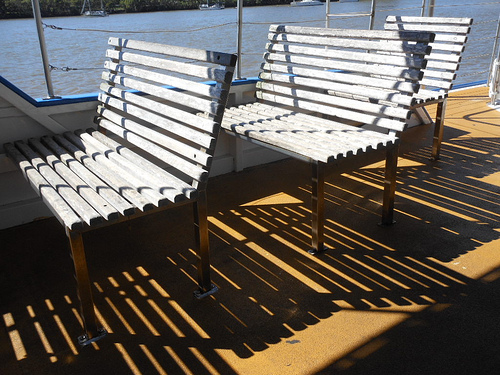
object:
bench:
[13, 36, 237, 346]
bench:
[208, 24, 433, 262]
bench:
[360, 14, 473, 162]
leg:
[65, 222, 99, 344]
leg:
[195, 194, 212, 295]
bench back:
[87, 36, 239, 166]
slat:
[99, 82, 207, 137]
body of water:
[0, 0, 488, 84]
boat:
[0, 0, 499, 375]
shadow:
[93, 215, 249, 375]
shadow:
[282, 165, 500, 263]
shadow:
[404, 139, 500, 192]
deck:
[7, 103, 500, 375]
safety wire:
[42, 21, 238, 34]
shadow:
[231, 25, 310, 128]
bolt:
[78, 335, 86, 340]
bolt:
[98, 328, 106, 333]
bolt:
[195, 289, 201, 294]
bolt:
[211, 283, 216, 287]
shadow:
[281, 205, 477, 306]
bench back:
[247, 24, 431, 131]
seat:
[21, 146, 193, 230]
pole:
[31, 0, 58, 101]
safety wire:
[47, 54, 236, 73]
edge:
[0, 69, 491, 105]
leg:
[308, 159, 329, 255]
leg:
[377, 146, 399, 229]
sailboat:
[79, 3, 110, 17]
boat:
[290, 0, 325, 7]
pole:
[234, 0, 246, 82]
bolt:
[309, 248, 315, 253]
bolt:
[323, 246, 328, 249]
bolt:
[378, 222, 383, 225]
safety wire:
[242, 13, 371, 24]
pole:
[364, 0, 376, 65]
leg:
[428, 98, 446, 162]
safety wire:
[240, 46, 347, 56]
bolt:
[428, 157, 433, 160]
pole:
[323, 0, 330, 70]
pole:
[486, 16, 499, 80]